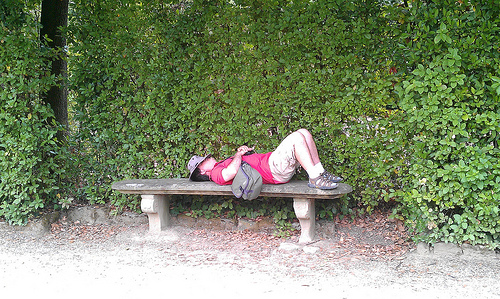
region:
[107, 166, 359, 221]
a concrete bench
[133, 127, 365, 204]
a man laying down on a bench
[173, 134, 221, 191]
a covering his face with a hat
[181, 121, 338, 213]
a man wearing tan shorts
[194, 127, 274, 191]
a man wearing a red shirt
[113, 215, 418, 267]
brown leaves on the ground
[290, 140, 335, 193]
a man wearing white socks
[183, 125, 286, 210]
a man with a bag by his side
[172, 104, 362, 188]
a man with his knees raised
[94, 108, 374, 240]
a man sleeping on a bench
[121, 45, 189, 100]
green foliage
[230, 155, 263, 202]
purple and sage green bag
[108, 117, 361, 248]
person sleeping on bench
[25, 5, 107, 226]
ivy climbing a wall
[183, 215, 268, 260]
dead leaves on ground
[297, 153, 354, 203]
feet with socks in sandals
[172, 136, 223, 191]
hat over face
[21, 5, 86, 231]
side entry into a garden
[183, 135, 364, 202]
sleeping with hands on chest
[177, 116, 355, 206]
man slumbering in a red shirt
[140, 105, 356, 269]
man laying on a concrete park bench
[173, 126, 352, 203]
man wearing a hat over his face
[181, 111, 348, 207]
man wearing socks and sandals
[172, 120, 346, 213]
man wearing a red t-shirt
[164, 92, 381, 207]
man wearing khaki shorts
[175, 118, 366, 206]
man holding a tan satchel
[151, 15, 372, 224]
green bushes behind a man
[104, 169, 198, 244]
concrete park bench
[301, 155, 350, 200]
white socks and tan sandals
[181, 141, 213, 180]
brown hat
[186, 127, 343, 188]
A person in a red shirt laying on a bench.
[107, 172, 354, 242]
A concrete bench with a person lying on it.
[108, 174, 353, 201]
Darker concrete slab on concrete legs.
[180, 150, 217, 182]
Hat covering most of a persons face.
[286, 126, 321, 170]
Bare legs of a person lying down.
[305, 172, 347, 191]
Brown sandals on a person taking a nap.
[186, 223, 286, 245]
Brown leaves under a concrete bench.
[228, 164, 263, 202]
A gray pack hanging off an arm of a person lying on a bench.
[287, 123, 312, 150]
White knees on a man lying down taking a nap.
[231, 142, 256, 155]
Hands resting on the stomach of a person lying down.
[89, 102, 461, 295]
a person laying on a bench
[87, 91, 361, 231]
a person laying on a cement bench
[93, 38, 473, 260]
a person laying outside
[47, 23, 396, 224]
a person laying outside on the bench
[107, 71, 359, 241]
a person laying on a bench outside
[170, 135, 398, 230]
a person wearing a hat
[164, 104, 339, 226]
a person wearing a bag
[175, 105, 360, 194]
a person wearing a red shirt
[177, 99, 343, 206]
a person wearing a shirt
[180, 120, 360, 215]
a person wearing sandels